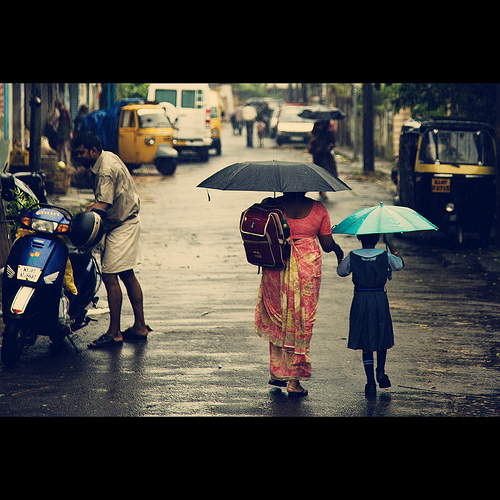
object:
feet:
[87, 324, 125, 353]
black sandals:
[86, 322, 124, 357]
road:
[0, 115, 499, 419]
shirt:
[331, 245, 402, 278]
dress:
[345, 245, 396, 357]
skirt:
[250, 235, 322, 381]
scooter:
[0, 204, 105, 357]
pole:
[358, 80, 381, 177]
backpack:
[235, 196, 294, 275]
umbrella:
[327, 203, 440, 241]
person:
[250, 191, 344, 399]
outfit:
[87, 147, 142, 273]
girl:
[330, 228, 404, 400]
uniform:
[333, 245, 405, 354]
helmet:
[66, 199, 106, 250]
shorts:
[93, 207, 144, 277]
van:
[140, 84, 214, 161]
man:
[66, 132, 152, 353]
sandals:
[283, 368, 310, 397]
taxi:
[391, 112, 498, 263]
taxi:
[96, 88, 181, 183]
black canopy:
[192, 156, 352, 203]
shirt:
[87, 150, 140, 224]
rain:
[155, 212, 232, 357]